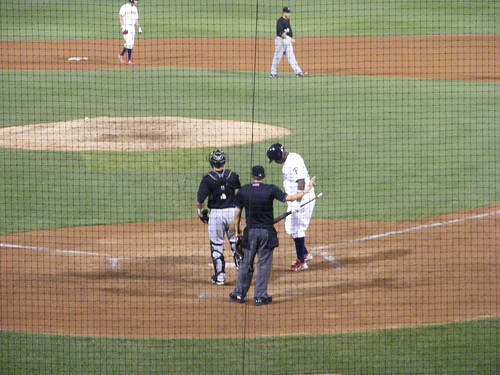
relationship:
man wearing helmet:
[254, 144, 331, 260] [251, 134, 298, 166]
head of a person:
[265, 139, 290, 165] [266, 142, 317, 273]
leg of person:
[228, 245, 252, 290] [179, 142, 254, 282]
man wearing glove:
[111, 3, 156, 70] [116, 26, 129, 36]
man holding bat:
[266, 142, 321, 273] [261, 194, 331, 224]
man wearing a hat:
[262, 4, 314, 86] [267, 2, 306, 15]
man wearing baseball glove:
[196, 151, 243, 286] [197, 210, 207, 225]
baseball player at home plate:
[266, 142, 317, 272] [204, 255, 255, 275]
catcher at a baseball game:
[197, 147, 244, 289] [10, 10, 487, 360]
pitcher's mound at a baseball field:
[118, 177, 375, 315] [42, 56, 483, 358]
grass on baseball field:
[0, 1, 497, 373] [42, 56, 483, 358]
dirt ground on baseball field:
[331, 229, 476, 328] [42, 56, 483, 358]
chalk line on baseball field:
[316, 209, 498, 249] [42, 56, 483, 358]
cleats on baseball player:
[285, 244, 323, 286] [243, 127, 339, 282]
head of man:
[249, 4, 310, 26] [270, 4, 308, 79]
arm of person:
[291, 158, 304, 212] [266, 142, 317, 273]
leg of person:
[208, 225, 224, 290] [193, 147, 238, 286]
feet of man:
[211, 274, 225, 283] [196, 149, 243, 286]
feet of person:
[292, 70, 314, 80] [258, 0, 316, 83]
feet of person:
[266, 70, 283, 80] [258, 0, 316, 83]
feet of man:
[247, 293, 274, 307] [230, 162, 318, 306]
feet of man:
[227, 282, 246, 302] [230, 162, 318, 306]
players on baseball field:
[182, 121, 342, 301] [42, 56, 483, 358]